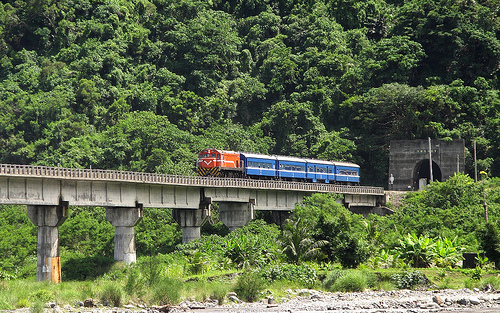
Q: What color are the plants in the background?
A: Green.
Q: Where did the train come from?
A: The tunnel.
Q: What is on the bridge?
A: A train.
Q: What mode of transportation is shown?
A: Train.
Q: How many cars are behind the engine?
A: 4.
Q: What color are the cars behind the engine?
A: Blue.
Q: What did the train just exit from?
A: Tunnel.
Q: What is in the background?
A: Trees.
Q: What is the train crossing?
A: Bridge.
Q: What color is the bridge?
A: Gray.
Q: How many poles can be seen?
A: 3.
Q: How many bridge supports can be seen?
A: 3.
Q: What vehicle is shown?
A: A train.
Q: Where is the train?
A: On the bridge.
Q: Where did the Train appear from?
A: The tunnel.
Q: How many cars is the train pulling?
A: Three.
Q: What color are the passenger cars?
A: Blue.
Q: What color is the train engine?
A: Orange.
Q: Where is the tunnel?
A: Behind the train.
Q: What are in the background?
A: Trees.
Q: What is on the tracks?
A: Train.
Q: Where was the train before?
A: In the tunnel.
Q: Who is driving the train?
A: Conductor.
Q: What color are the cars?
A: Blue.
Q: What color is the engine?
A: Orange.